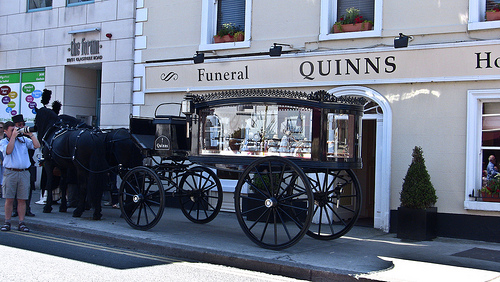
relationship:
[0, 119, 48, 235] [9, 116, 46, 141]
man holding camera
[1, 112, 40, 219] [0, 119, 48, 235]
man standing behind man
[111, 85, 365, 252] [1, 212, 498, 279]
carriage on road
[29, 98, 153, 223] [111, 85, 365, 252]
horses with carriage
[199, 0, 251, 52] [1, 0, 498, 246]
window on building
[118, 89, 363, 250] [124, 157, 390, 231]
carriage on wheels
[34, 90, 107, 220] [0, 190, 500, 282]
black horse on side walk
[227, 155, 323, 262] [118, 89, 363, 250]
wheel of carriage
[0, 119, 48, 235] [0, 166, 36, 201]
man wearing shorts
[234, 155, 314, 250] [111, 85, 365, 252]
wheel on carriage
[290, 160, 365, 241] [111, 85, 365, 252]
wheel on carriage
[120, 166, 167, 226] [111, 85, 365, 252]
wheel on carriage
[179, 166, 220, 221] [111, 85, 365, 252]
wheel on carriage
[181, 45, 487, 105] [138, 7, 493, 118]
words on building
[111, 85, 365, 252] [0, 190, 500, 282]
carriage on side walk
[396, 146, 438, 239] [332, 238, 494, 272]
tree on side walk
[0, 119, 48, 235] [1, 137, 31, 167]
man wearing shirt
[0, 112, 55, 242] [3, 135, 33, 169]
man wearing dress shirt